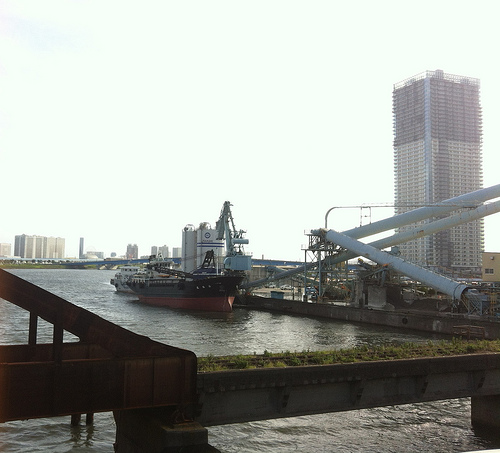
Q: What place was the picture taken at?
A: It was taken at the river.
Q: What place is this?
A: It is a river.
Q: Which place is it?
A: It is a river.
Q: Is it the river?
A: Yes, it is the river.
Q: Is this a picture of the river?
A: Yes, it is showing the river.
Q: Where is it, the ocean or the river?
A: It is the river.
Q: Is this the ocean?
A: No, it is the river.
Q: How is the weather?
A: It is overcast.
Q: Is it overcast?
A: Yes, it is overcast.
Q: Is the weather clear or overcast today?
A: It is overcast.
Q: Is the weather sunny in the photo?
A: No, it is overcast.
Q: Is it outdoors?
A: Yes, it is outdoors.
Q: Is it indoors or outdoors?
A: It is outdoors.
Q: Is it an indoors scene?
A: No, it is outdoors.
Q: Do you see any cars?
A: No, there are no cars.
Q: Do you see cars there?
A: No, there are no cars.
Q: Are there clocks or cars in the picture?
A: No, there are no cars or clocks.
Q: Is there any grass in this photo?
A: Yes, there is grass.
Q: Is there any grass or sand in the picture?
A: Yes, there is grass.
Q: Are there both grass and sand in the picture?
A: No, there is grass but no sand.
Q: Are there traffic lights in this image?
A: No, there are no traffic lights.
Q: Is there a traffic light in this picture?
A: No, there are no traffic lights.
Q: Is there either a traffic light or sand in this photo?
A: No, there are no traffic lights or sand.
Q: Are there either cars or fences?
A: No, there are no cars or fences.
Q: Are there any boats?
A: Yes, there is a boat.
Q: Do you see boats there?
A: Yes, there is a boat.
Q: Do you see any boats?
A: Yes, there is a boat.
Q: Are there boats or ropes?
A: Yes, there is a boat.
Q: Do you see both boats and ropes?
A: No, there is a boat but no ropes.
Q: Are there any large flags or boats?
A: Yes, there is a large boat.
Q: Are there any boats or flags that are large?
A: Yes, the boat is large.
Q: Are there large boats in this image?
A: Yes, there is a large boat.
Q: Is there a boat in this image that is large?
A: Yes, there is a boat that is large.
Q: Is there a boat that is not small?
A: Yes, there is a large boat.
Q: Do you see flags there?
A: No, there are no flags.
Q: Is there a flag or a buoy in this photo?
A: No, there are no flags or buoys.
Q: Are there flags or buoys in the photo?
A: No, there are no flags or buoys.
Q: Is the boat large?
A: Yes, the boat is large.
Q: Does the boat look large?
A: Yes, the boat is large.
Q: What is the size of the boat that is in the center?
A: The boat is large.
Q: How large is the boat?
A: The boat is large.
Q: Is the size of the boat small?
A: No, the boat is large.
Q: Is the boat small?
A: No, the boat is large.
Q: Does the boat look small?
A: No, the boat is large.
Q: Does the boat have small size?
A: No, the boat is large.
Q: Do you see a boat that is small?
A: No, there is a boat but it is large.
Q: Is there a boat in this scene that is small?
A: No, there is a boat but it is large.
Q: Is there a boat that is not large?
A: No, there is a boat but it is large.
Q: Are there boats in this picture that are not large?
A: No, there is a boat but it is large.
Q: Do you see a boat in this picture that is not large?
A: No, there is a boat but it is large.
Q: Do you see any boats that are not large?
A: No, there is a boat but it is large.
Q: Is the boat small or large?
A: The boat is large.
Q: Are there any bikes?
A: No, there are no bikes.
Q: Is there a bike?
A: No, there are no bikes.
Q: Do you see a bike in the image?
A: No, there are no bikes.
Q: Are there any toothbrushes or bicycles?
A: No, there are no bicycles or toothbrushes.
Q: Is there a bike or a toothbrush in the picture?
A: No, there are no bikes or toothbrushes.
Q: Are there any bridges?
A: Yes, there is a bridge.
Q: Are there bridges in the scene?
A: Yes, there is a bridge.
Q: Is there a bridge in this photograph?
A: Yes, there is a bridge.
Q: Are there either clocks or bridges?
A: Yes, there is a bridge.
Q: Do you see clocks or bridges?
A: Yes, there is a bridge.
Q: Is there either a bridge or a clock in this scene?
A: Yes, there is a bridge.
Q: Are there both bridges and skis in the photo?
A: No, there is a bridge but no skis.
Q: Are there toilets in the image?
A: No, there are no toilets.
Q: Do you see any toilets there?
A: No, there are no toilets.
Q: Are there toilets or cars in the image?
A: No, there are no toilets or cars.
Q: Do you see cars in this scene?
A: No, there are no cars.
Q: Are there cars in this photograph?
A: No, there are no cars.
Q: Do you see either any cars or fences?
A: No, there are no cars or fences.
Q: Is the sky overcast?
A: Yes, the sky is overcast.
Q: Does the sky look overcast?
A: Yes, the sky is overcast.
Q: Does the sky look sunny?
A: No, the sky is overcast.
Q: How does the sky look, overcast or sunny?
A: The sky is overcast.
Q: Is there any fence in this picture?
A: No, there are no fences.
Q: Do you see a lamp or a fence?
A: No, there are no fences or lamps.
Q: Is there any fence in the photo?
A: No, there are no fences.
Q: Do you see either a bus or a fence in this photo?
A: No, there are no fences or buses.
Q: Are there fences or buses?
A: No, there are no fences or buses.